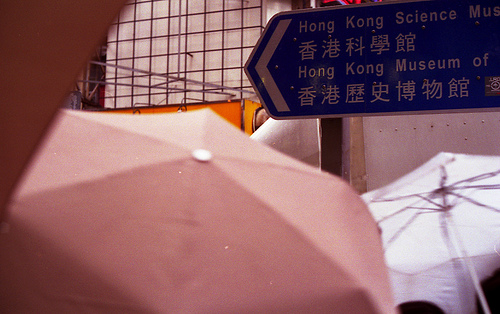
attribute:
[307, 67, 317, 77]
letter o — white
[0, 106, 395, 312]
umbrella — pink, open, brown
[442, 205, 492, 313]
handle — silver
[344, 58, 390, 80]
kong — white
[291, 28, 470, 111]
letters — Japanese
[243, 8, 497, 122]
sign — blue, white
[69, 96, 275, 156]
wall — orange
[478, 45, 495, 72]
letter f — white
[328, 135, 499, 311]
umbrella — white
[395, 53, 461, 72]
word — white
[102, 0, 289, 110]
wall — textured, white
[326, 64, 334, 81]
g — white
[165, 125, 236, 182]
cap — white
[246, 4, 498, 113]
street sign — blue, white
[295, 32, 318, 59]
character — chinese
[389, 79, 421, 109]
character — chinese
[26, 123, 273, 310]
umbrella — pink